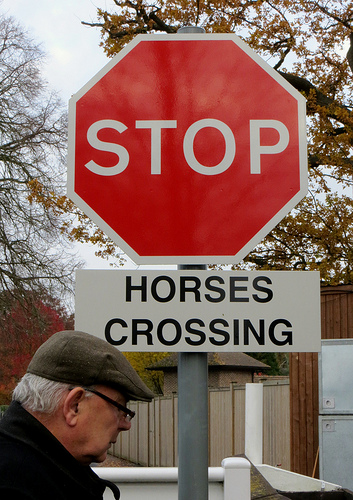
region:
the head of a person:
[19, 333, 162, 461]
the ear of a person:
[58, 381, 99, 437]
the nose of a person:
[102, 400, 152, 441]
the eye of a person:
[103, 391, 138, 419]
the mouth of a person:
[92, 425, 128, 448]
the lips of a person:
[88, 427, 136, 469]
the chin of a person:
[74, 427, 117, 497]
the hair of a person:
[12, 365, 80, 436]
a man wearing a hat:
[21, 320, 186, 408]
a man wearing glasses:
[78, 383, 181, 450]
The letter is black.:
[120, 270, 149, 305]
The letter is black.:
[148, 270, 176, 306]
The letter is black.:
[176, 272, 204, 304]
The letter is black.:
[201, 269, 226, 305]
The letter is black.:
[224, 269, 251, 307]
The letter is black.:
[248, 268, 275, 307]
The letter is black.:
[101, 310, 130, 344]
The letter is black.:
[181, 311, 208, 349]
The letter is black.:
[204, 312, 231, 348]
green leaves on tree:
[130, 353, 155, 368]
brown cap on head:
[45, 329, 154, 389]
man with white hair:
[26, 380, 98, 404]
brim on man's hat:
[128, 381, 169, 401]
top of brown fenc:
[217, 375, 251, 398]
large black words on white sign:
[116, 275, 285, 327]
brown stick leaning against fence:
[303, 447, 322, 478]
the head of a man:
[28, 333, 154, 441]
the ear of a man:
[48, 374, 97, 423]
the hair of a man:
[10, 324, 107, 423]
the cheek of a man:
[77, 397, 119, 456]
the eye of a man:
[107, 391, 132, 406]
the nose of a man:
[104, 409, 146, 437]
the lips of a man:
[97, 426, 131, 451]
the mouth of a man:
[98, 432, 131, 455]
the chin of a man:
[84, 441, 111, 470]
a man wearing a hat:
[40, 347, 183, 428]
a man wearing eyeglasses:
[24, 330, 168, 460]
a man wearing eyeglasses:
[14, 309, 161, 443]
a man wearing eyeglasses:
[23, 314, 153, 449]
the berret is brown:
[27, 316, 166, 417]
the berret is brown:
[19, 315, 152, 405]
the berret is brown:
[19, 324, 177, 428]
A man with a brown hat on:
[40, 316, 148, 447]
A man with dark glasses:
[55, 384, 165, 421]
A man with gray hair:
[15, 358, 95, 427]